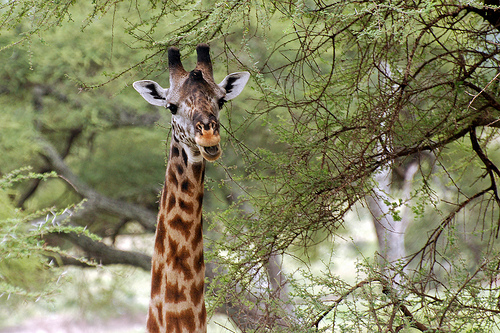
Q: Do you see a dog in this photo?
A: No, there are no dogs.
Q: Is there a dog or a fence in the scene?
A: No, there are no dogs or fences.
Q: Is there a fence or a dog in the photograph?
A: No, there are no dogs or fences.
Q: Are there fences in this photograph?
A: No, there are no fences.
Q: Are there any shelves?
A: No, there are no shelves.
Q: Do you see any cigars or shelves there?
A: No, there are no shelves or cigars.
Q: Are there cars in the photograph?
A: No, there are no cars.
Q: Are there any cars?
A: No, there are no cars.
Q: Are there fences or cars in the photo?
A: No, there are no cars or fences.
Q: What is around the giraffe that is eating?
A: The trees are around the giraffe.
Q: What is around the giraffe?
A: The trees are around the giraffe.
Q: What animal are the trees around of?
A: The trees are around the giraffe.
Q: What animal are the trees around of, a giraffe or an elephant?
A: The trees are around a giraffe.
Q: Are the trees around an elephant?
A: No, the trees are around the giraffe.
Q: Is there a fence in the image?
A: No, there are no fences.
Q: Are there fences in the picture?
A: No, there are no fences.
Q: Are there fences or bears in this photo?
A: No, there are no fences or bears.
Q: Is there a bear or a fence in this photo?
A: No, there are no fences or bears.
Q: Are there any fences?
A: No, there are no fences.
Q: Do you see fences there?
A: No, there are no fences.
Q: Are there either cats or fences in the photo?
A: No, there are no fences or cats.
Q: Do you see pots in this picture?
A: No, there are no pots.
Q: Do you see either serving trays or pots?
A: No, there are no pots or serving trays.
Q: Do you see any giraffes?
A: Yes, there is a giraffe.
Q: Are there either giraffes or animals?
A: Yes, there is a giraffe.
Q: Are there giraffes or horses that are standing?
A: Yes, the giraffe is standing.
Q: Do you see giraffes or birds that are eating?
A: Yes, the giraffe is eating.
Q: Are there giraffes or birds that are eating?
A: Yes, the giraffe is eating.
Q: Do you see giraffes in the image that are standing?
A: Yes, there is a giraffe that is standing.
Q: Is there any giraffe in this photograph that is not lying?
A: Yes, there is a giraffe that is standing.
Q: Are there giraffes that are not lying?
A: Yes, there is a giraffe that is standing.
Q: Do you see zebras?
A: No, there are no zebras.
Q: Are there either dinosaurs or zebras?
A: No, there are no zebras or dinosaurs.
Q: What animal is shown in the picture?
A: The animal is a giraffe.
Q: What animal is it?
A: The animal is a giraffe.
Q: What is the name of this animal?
A: This is a giraffe.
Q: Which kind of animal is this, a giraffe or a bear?
A: This is a giraffe.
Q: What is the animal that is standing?
A: The animal is a giraffe.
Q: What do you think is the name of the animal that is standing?
A: The animal is a giraffe.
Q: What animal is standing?
A: The animal is a giraffe.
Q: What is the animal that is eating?
A: The animal is a giraffe.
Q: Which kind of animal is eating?
A: The animal is a giraffe.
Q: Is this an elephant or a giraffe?
A: This is a giraffe.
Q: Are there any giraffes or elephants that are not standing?
A: No, there is a giraffe but it is standing.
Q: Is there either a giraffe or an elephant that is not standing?
A: No, there is a giraffe but it is standing.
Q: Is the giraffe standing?
A: Yes, the giraffe is standing.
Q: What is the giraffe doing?
A: The giraffe is standing.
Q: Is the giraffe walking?
A: No, the giraffe is standing.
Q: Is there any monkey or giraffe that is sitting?
A: No, there is a giraffe but it is standing.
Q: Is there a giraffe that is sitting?
A: No, there is a giraffe but it is standing.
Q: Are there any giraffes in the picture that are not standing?
A: No, there is a giraffe but it is standing.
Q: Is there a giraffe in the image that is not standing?
A: No, there is a giraffe but it is standing.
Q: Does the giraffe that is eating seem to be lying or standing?
A: The giraffe is standing.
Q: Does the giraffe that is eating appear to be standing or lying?
A: The giraffe is standing.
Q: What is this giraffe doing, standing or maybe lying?
A: The giraffe is standing.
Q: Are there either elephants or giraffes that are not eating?
A: No, there is a giraffe but it is eating.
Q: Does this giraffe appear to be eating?
A: Yes, the giraffe is eating.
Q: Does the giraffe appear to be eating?
A: Yes, the giraffe is eating.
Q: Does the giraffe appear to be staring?
A: No, the giraffe is eating.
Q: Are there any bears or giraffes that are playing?
A: No, there is a giraffe but it is eating.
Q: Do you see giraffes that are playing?
A: No, there is a giraffe but it is eating.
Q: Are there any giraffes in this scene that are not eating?
A: No, there is a giraffe but it is eating.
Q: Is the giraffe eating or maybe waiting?
A: The giraffe is eating.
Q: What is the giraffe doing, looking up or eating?
A: The giraffe is eating.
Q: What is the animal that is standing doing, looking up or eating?
A: The giraffe is eating.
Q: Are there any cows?
A: No, there are no cows.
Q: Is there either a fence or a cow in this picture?
A: No, there are no cows or fences.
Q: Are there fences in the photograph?
A: No, there are no fences.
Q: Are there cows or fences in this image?
A: No, there are no fences or cows.